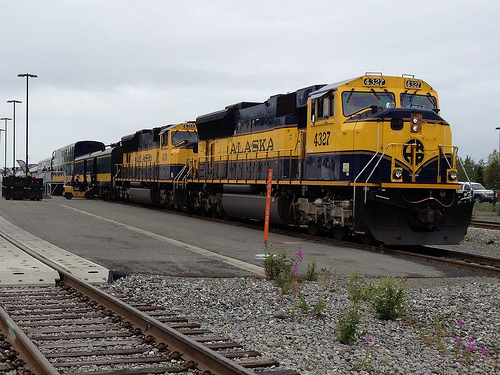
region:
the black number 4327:
[308, 126, 341, 148]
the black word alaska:
[222, 135, 278, 157]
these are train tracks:
[0, 216, 300, 373]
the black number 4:
[310, 129, 322, 149]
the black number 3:
[316, 131, 326, 151]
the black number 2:
[318, 127, 332, 148]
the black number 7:
[323, 127, 333, 147]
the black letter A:
[226, 142, 238, 156]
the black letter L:
[234, 136, 249, 158]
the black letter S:
[248, 135, 260, 155]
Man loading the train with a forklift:
[56, 170, 115, 205]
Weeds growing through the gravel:
[242, 262, 422, 347]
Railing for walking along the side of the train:
[150, 141, 332, 186]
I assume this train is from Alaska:
[107, 87, 477, 271]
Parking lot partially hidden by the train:
[458, 167, 498, 220]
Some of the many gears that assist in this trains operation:
[288, 191, 365, 239]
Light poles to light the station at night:
[14, 65, 50, 182]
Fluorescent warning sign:
[248, 162, 279, 264]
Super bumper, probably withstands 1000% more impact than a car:
[334, 176, 489, 256]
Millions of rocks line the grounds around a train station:
[446, 287, 493, 331]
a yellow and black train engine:
[188, 64, 467, 249]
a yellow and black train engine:
[114, 125, 191, 202]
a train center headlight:
[406, 111, 421, 130]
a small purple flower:
[282, 244, 304, 292]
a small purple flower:
[453, 319, 490, 369]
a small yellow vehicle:
[60, 176, 97, 201]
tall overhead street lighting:
[8, 97, 20, 165]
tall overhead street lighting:
[0, 113, 10, 174]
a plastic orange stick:
[257, 166, 279, 263]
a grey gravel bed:
[131, 276, 497, 373]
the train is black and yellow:
[53, 102, 471, 237]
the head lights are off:
[360, 152, 468, 186]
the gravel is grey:
[146, 257, 398, 369]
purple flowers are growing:
[433, 305, 487, 363]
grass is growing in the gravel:
[266, 272, 421, 327]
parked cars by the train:
[440, 171, 496, 201]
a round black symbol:
[364, 135, 432, 175]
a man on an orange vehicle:
[37, 152, 96, 202]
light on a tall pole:
[11, 47, 51, 177]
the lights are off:
[0, 54, 64, 140]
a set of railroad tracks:
[0, 222, 273, 371]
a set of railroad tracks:
[377, 228, 499, 280]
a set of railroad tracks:
[464, 214, 497, 232]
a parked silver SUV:
[456, 175, 495, 204]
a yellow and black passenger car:
[70, 140, 128, 199]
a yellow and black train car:
[50, 140, 101, 192]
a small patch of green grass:
[334, 305, 361, 346]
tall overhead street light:
[15, 69, 35, 164]